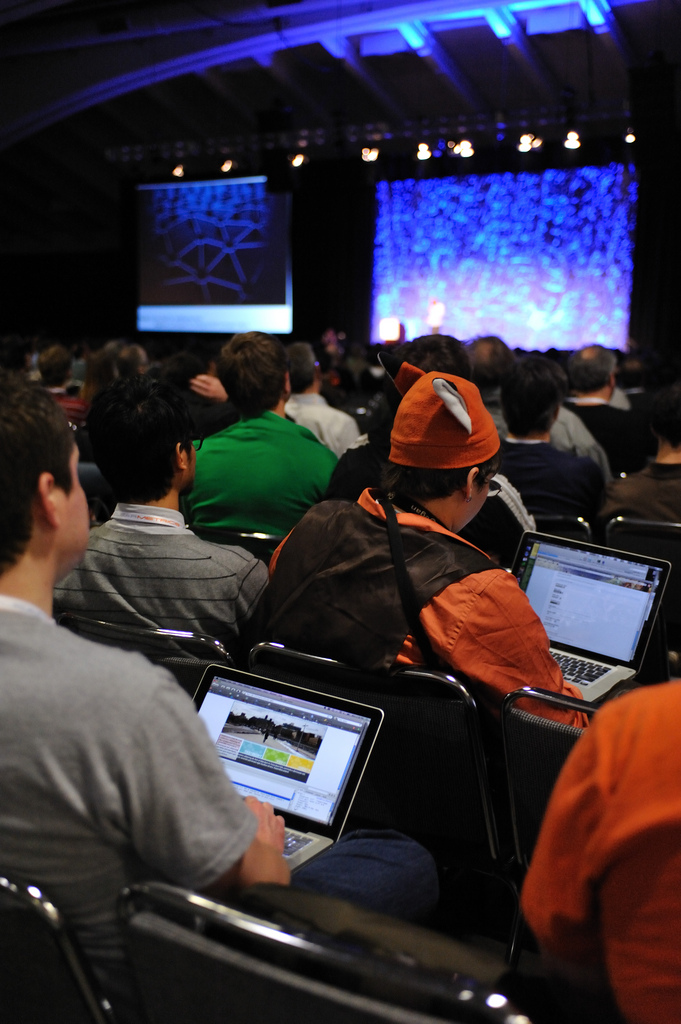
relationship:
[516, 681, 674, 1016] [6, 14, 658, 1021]
person sitting in theatre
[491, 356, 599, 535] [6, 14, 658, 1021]
person sitting in theatre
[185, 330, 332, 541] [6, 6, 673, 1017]
person sitting in theater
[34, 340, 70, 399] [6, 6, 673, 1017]
person sitting in theater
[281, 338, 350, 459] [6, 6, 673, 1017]
person sitting in theater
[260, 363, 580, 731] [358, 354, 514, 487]
man wearing a hat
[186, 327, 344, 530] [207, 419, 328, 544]
man wearing a polo shirt